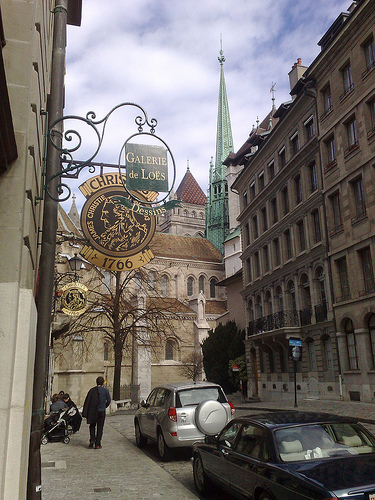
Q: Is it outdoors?
A: Yes, it is outdoors.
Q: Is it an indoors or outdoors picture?
A: It is outdoors.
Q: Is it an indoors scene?
A: No, it is outdoors.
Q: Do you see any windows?
A: Yes, there is a window.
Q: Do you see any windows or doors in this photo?
A: Yes, there is a window.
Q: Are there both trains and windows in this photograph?
A: No, there is a window but no trains.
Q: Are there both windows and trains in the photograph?
A: No, there is a window but no trains.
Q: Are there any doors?
A: No, there are no doors.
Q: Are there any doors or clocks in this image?
A: No, there are no doors or clocks.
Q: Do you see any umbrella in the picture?
A: No, there are no umbrellas.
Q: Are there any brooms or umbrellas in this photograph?
A: No, there are no umbrellas or brooms.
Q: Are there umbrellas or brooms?
A: No, there are no umbrellas or brooms.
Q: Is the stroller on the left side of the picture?
A: Yes, the stroller is on the left of the image.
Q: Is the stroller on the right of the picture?
A: No, the stroller is on the left of the image.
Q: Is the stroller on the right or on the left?
A: The stroller is on the left of the image.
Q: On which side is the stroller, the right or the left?
A: The stroller is on the left of the image.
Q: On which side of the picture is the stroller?
A: The stroller is on the left of the image.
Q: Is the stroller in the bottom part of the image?
A: Yes, the stroller is in the bottom of the image.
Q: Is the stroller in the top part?
A: No, the stroller is in the bottom of the image.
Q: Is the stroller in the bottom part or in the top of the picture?
A: The stroller is in the bottom of the image.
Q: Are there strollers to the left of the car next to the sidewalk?
A: Yes, there is a stroller to the left of the car.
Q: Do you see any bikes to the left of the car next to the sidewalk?
A: No, there is a stroller to the left of the car.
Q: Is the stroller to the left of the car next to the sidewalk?
A: Yes, the stroller is to the left of the car.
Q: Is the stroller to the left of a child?
A: No, the stroller is to the left of the car.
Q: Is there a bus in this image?
A: No, there are no buses.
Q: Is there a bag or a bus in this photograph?
A: No, there are no buses or bags.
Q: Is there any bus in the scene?
A: No, there are no buses.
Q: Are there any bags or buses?
A: No, there are no buses or bags.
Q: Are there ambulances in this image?
A: No, there are no ambulances.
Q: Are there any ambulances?
A: No, there are no ambulances.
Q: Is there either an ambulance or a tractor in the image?
A: No, there are no ambulances or tractors.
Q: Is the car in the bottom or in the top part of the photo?
A: The car is in the bottom of the image.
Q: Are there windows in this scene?
A: Yes, there is a window.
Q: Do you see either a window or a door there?
A: Yes, there is a window.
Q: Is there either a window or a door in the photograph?
A: Yes, there is a window.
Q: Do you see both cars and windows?
A: Yes, there are both a window and a car.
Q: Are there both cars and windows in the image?
A: Yes, there are both a window and a car.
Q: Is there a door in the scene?
A: No, there are no doors.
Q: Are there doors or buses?
A: No, there are no doors or buses.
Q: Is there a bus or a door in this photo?
A: No, there are no doors or buses.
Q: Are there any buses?
A: No, there are no buses.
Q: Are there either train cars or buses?
A: No, there are no buses or train cars.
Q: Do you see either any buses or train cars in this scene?
A: No, there are no buses or train cars.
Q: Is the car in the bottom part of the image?
A: Yes, the car is in the bottom of the image.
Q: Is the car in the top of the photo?
A: No, the car is in the bottom of the image.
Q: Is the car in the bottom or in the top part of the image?
A: The car is in the bottom of the image.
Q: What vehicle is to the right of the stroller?
A: The vehicle is a car.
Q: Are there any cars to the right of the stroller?
A: Yes, there is a car to the right of the stroller.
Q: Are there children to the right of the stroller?
A: No, there is a car to the right of the stroller.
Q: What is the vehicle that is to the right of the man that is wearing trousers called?
A: The vehicle is a car.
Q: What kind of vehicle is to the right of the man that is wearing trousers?
A: The vehicle is a car.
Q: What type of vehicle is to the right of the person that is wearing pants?
A: The vehicle is a car.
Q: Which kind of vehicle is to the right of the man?
A: The vehicle is a car.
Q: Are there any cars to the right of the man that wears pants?
A: Yes, there is a car to the right of the man.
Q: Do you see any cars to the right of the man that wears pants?
A: Yes, there is a car to the right of the man.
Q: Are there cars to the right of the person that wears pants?
A: Yes, there is a car to the right of the man.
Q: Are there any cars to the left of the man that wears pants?
A: No, the car is to the right of the man.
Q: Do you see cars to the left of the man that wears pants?
A: No, the car is to the right of the man.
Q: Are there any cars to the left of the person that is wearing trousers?
A: No, the car is to the right of the man.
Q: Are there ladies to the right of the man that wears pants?
A: No, there is a car to the right of the man.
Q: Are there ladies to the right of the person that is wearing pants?
A: No, there is a car to the right of the man.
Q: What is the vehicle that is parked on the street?
A: The vehicle is a car.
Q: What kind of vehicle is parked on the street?
A: The vehicle is a car.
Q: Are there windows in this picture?
A: Yes, there is a window.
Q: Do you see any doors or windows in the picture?
A: Yes, there is a window.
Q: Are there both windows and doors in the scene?
A: No, there is a window but no doors.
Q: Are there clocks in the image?
A: No, there are no clocks.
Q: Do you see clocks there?
A: No, there are no clocks.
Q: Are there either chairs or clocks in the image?
A: No, there are no clocks or chairs.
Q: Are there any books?
A: No, there are no books.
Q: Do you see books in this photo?
A: No, there are no books.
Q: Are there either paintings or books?
A: No, there are no books or paintings.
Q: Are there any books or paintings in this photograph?
A: No, there are no books or paintings.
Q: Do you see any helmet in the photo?
A: No, there are no helmets.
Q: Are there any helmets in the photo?
A: No, there are no helmets.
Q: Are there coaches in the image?
A: No, there are no coaches.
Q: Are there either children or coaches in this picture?
A: No, there are no coaches or children.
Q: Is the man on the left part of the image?
A: Yes, the man is on the left of the image.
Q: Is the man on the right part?
A: No, the man is on the left of the image.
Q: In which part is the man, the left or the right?
A: The man is on the left of the image.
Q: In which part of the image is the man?
A: The man is on the left of the image.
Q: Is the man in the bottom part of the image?
A: Yes, the man is in the bottom of the image.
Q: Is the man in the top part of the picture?
A: No, the man is in the bottom of the image.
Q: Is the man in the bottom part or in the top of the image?
A: The man is in the bottom of the image.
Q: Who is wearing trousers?
A: The man is wearing trousers.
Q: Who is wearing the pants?
A: The man is wearing trousers.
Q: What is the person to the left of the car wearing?
A: The man is wearing pants.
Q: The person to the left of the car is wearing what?
A: The man is wearing pants.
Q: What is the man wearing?
A: The man is wearing pants.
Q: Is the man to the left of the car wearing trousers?
A: Yes, the man is wearing trousers.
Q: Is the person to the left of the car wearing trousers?
A: Yes, the man is wearing trousers.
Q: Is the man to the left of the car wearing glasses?
A: No, the man is wearing trousers.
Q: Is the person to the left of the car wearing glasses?
A: No, the man is wearing trousers.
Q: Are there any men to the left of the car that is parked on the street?
A: Yes, there is a man to the left of the car.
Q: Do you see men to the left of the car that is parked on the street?
A: Yes, there is a man to the left of the car.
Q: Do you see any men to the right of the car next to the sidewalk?
A: No, the man is to the left of the car.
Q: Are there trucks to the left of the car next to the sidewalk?
A: No, there is a man to the left of the car.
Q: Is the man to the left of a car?
A: Yes, the man is to the left of a car.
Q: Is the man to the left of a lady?
A: No, the man is to the left of a car.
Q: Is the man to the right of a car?
A: No, the man is to the left of a car.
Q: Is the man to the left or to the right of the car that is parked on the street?
A: The man is to the left of the car.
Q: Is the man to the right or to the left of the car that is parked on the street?
A: The man is to the left of the car.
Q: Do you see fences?
A: Yes, there is a fence.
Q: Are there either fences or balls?
A: Yes, there is a fence.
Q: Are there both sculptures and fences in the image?
A: No, there is a fence but no sculptures.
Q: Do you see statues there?
A: No, there are no statues.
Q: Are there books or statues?
A: No, there are no statues or books.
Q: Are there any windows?
A: Yes, there is a window.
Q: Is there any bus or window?
A: Yes, there is a window.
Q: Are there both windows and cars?
A: Yes, there are both a window and a car.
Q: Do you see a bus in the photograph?
A: No, there are no buses.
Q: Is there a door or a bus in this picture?
A: No, there are no buses or doors.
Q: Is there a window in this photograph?
A: Yes, there is a window.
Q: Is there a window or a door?
A: Yes, there is a window.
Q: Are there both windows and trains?
A: No, there is a window but no trains.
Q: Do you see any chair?
A: No, there are no chairs.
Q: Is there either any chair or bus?
A: No, there are no chairs or buses.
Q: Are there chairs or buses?
A: No, there are no chairs or buses.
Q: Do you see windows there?
A: Yes, there is a window.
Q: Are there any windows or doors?
A: Yes, there is a window.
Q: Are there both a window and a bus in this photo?
A: No, there is a window but no buses.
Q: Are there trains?
A: No, there are no trains.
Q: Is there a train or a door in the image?
A: No, there are no trains or doors.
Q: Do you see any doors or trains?
A: No, there are no trains or doors.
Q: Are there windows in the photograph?
A: Yes, there is a window.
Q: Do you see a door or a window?
A: Yes, there is a window.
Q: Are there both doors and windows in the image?
A: No, there is a window but no doors.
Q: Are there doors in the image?
A: No, there are no doors.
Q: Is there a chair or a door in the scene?
A: No, there are no doors or chairs.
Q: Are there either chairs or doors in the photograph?
A: No, there are no doors or chairs.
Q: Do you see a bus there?
A: No, there are no buses.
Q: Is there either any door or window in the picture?
A: Yes, there is a window.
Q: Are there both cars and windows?
A: Yes, there are both a window and a car.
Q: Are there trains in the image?
A: No, there are no trains.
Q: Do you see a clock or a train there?
A: No, there are no trains or clocks.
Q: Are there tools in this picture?
A: No, there are no tools.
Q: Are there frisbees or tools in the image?
A: No, there are no tools or frisbees.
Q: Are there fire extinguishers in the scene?
A: No, there are no fire extinguishers.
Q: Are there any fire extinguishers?
A: No, there are no fire extinguishers.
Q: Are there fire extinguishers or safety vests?
A: No, there are no fire extinguishers or safety vests.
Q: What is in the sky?
A: The clouds are in the sky.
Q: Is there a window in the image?
A: Yes, there is a window.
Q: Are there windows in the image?
A: Yes, there is a window.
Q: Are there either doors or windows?
A: Yes, there is a window.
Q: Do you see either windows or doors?
A: Yes, there is a window.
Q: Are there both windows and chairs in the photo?
A: No, there is a window but no chairs.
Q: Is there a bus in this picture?
A: No, there are no buses.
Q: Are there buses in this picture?
A: No, there are no buses.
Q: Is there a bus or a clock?
A: No, there are no buses or clocks.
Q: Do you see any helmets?
A: No, there are no helmets.